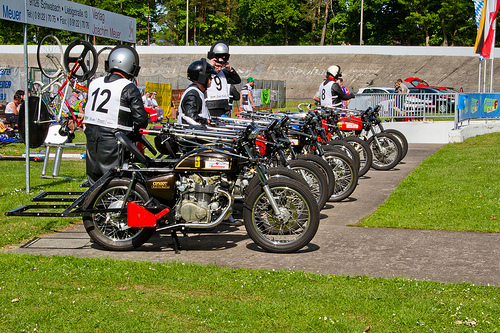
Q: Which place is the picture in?
A: It is at the path.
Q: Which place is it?
A: It is a path.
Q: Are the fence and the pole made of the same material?
A: Yes, both the fence and the pole are made of metal.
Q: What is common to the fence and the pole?
A: The material, both the fence and the pole are metallic.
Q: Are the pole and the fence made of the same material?
A: Yes, both the pole and the fence are made of metal.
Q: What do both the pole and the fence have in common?
A: The material, both the pole and the fence are metallic.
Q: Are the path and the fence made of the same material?
A: No, the path is made of cement and the fence is made of metal.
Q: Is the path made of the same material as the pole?
A: No, the path is made of cement and the pole is made of metal.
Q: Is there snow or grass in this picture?
A: Yes, there is grass.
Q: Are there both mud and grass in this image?
A: No, there is grass but no mud.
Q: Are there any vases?
A: No, there are no vases.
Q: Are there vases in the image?
A: No, there are no vases.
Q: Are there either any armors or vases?
A: No, there are no vases or armors.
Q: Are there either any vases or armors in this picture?
A: No, there are no vases or armors.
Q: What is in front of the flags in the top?
A: The grass is in front of the flags.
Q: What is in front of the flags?
A: The grass is in front of the flags.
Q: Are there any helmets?
A: Yes, there is a helmet.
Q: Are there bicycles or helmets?
A: Yes, there is a helmet.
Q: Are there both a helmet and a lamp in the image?
A: No, there is a helmet but no lamps.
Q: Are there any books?
A: No, there are no books.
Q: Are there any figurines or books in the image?
A: No, there are no books or figurines.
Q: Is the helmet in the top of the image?
A: Yes, the helmet is in the top of the image.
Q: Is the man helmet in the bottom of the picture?
A: No, the helmet is in the top of the image.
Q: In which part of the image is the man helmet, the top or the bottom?
A: The helmet is in the top of the image.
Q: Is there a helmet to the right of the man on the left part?
A: Yes, there is a helmet to the right of the man.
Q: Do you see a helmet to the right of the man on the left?
A: Yes, there is a helmet to the right of the man.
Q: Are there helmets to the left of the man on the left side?
A: No, the helmet is to the right of the man.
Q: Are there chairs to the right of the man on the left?
A: No, there is a helmet to the right of the man.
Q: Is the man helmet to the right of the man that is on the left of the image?
A: Yes, the helmet is to the right of the man.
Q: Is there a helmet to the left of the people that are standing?
A: Yes, there is a helmet to the left of the people.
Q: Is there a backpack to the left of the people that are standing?
A: No, there is a helmet to the left of the people.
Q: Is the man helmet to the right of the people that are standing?
A: No, the helmet is to the left of the people.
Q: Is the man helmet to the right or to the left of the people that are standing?
A: The helmet is to the left of the people.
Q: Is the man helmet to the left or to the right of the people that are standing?
A: The helmet is to the left of the people.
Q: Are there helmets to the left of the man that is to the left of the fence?
A: Yes, there is a helmet to the left of the man.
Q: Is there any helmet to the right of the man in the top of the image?
A: No, the helmet is to the left of the man.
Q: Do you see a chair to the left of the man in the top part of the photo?
A: No, there is a helmet to the left of the man.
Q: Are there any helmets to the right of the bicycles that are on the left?
A: Yes, there is a helmet to the right of the bikes.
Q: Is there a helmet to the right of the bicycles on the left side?
A: Yes, there is a helmet to the right of the bikes.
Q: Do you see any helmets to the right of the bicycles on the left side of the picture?
A: Yes, there is a helmet to the right of the bikes.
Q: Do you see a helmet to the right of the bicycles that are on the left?
A: Yes, there is a helmet to the right of the bikes.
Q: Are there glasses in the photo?
A: No, there are no glasses.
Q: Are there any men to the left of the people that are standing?
A: Yes, there is a man to the left of the people.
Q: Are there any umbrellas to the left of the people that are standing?
A: No, there is a man to the left of the people.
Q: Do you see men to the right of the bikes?
A: Yes, there is a man to the right of the bikes.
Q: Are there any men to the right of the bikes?
A: Yes, there is a man to the right of the bikes.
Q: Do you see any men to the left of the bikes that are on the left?
A: No, the man is to the right of the bikes.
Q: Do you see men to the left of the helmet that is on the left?
A: No, the man is to the right of the helmet.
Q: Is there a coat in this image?
A: Yes, there is a coat.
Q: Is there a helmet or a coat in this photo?
A: Yes, there is a coat.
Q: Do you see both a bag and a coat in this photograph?
A: No, there is a coat but no bags.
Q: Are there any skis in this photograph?
A: No, there are no skis.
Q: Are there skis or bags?
A: No, there are no skis or bags.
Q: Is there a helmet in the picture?
A: Yes, there is a helmet.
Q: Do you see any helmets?
A: Yes, there is a helmet.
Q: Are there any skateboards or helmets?
A: Yes, there is a helmet.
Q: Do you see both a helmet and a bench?
A: No, there is a helmet but no benches.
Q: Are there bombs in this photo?
A: No, there are no bombs.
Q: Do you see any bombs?
A: No, there are no bombs.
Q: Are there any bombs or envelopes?
A: No, there are no bombs or envelopes.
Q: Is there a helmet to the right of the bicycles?
A: Yes, there is a helmet to the right of the bicycles.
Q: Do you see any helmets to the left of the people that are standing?
A: Yes, there is a helmet to the left of the people.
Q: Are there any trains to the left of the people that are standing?
A: No, there is a helmet to the left of the people.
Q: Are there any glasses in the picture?
A: No, there are no glasses.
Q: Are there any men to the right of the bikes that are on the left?
A: Yes, there is a man to the right of the bikes.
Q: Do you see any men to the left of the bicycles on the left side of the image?
A: No, the man is to the right of the bikes.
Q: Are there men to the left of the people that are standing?
A: Yes, there is a man to the left of the people.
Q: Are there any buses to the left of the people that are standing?
A: No, there is a man to the left of the people.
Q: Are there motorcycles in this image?
A: Yes, there is a motorcycle.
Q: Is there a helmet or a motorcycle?
A: Yes, there is a motorcycle.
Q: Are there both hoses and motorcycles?
A: No, there is a motorcycle but no hoses.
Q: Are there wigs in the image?
A: No, there are no wigs.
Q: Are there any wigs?
A: No, there are no wigs.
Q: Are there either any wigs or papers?
A: No, there are no wigs or papers.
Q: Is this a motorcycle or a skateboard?
A: This is a motorcycle.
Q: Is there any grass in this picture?
A: Yes, there is grass.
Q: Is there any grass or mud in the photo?
A: Yes, there is grass.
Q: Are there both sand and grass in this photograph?
A: No, there is grass but no sand.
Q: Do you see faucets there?
A: No, there are no faucets.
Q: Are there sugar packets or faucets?
A: No, there are no faucets or sugar packets.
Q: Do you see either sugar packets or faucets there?
A: No, there are no faucets or sugar packets.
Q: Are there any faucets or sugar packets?
A: No, there are no faucets or sugar packets.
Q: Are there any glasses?
A: No, there are no glasses.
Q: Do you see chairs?
A: No, there are no chairs.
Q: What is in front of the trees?
A: The wall is in front of the trees.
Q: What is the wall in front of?
A: The wall is in front of the trees.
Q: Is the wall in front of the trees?
A: Yes, the wall is in front of the trees.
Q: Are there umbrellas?
A: No, there are no umbrellas.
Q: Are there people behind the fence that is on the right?
A: Yes, there are people behind the fence.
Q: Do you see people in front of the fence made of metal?
A: No, the people are behind the fence.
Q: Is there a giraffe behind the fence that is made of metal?
A: No, there are people behind the fence.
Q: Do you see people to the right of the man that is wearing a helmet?
A: Yes, there are people to the right of the man.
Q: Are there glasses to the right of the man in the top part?
A: No, there are people to the right of the man.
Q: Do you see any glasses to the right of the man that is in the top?
A: No, there are people to the right of the man.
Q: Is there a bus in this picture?
A: No, there are no buses.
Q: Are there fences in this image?
A: Yes, there is a fence.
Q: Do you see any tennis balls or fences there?
A: Yes, there is a fence.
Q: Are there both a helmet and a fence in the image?
A: Yes, there are both a fence and a helmet.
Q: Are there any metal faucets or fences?
A: Yes, there is a metal fence.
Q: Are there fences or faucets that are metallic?
A: Yes, the fence is metallic.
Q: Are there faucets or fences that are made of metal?
A: Yes, the fence is made of metal.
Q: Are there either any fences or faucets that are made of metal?
A: Yes, the fence is made of metal.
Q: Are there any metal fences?
A: Yes, there is a metal fence.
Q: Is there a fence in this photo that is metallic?
A: Yes, there is a fence that is metallic.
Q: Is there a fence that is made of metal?
A: Yes, there is a fence that is made of metal.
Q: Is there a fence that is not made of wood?
A: Yes, there is a fence that is made of metal.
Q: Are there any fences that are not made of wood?
A: Yes, there is a fence that is made of metal.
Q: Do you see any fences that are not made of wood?
A: Yes, there is a fence that is made of metal.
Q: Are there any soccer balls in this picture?
A: No, there are no soccer balls.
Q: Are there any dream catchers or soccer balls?
A: No, there are no soccer balls or dream catchers.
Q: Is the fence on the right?
A: Yes, the fence is on the right of the image.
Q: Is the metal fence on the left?
A: No, the fence is on the right of the image.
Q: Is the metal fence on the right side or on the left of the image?
A: The fence is on the right of the image.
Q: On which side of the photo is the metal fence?
A: The fence is on the right of the image.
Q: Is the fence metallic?
A: Yes, the fence is metallic.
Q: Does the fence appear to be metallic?
A: Yes, the fence is metallic.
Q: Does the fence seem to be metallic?
A: Yes, the fence is metallic.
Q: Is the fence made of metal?
A: Yes, the fence is made of metal.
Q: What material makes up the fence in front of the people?
A: The fence is made of metal.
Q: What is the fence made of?
A: The fence is made of metal.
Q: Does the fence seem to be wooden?
A: No, the fence is metallic.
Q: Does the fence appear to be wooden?
A: No, the fence is metallic.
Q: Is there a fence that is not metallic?
A: No, there is a fence but it is metallic.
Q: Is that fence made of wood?
A: No, the fence is made of metal.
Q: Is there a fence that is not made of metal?
A: No, there is a fence but it is made of metal.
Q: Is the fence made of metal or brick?
A: The fence is made of metal.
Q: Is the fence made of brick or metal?
A: The fence is made of metal.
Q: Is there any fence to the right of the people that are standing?
A: Yes, there is a fence to the right of the people.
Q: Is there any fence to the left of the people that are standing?
A: No, the fence is to the right of the people.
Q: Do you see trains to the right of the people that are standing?
A: No, there is a fence to the right of the people.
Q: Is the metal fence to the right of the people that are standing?
A: Yes, the fence is to the right of the people.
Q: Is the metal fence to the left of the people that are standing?
A: No, the fence is to the right of the people.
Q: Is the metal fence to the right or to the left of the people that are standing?
A: The fence is to the right of the people.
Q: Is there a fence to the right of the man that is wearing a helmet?
A: Yes, there is a fence to the right of the man.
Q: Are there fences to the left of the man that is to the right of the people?
A: No, the fence is to the right of the man.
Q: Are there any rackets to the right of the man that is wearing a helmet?
A: No, there is a fence to the right of the man.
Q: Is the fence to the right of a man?
A: Yes, the fence is to the right of a man.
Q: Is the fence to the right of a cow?
A: No, the fence is to the right of a man.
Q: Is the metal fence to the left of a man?
A: No, the fence is to the right of a man.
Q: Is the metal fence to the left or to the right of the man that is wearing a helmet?
A: The fence is to the right of the man.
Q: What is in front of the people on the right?
A: The fence is in front of the people.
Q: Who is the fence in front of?
A: The fence is in front of the people.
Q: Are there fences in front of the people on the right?
A: Yes, there is a fence in front of the people.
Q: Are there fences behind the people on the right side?
A: No, the fence is in front of the people.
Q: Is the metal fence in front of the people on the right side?
A: Yes, the fence is in front of the people.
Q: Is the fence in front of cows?
A: No, the fence is in front of the people.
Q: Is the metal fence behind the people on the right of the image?
A: No, the fence is in front of the people.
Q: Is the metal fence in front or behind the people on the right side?
A: The fence is in front of the people.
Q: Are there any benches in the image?
A: No, there are no benches.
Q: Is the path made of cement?
A: Yes, the path is made of cement.